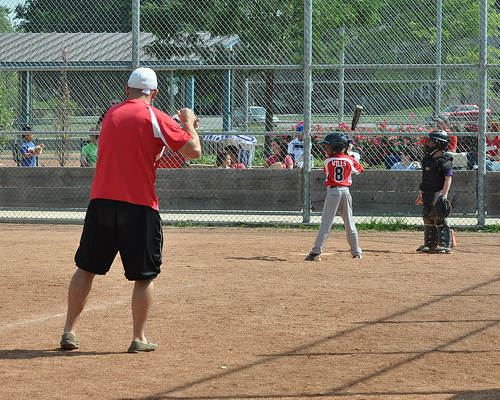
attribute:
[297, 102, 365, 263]
player — young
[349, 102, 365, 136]
bat — black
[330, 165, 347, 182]
number — #8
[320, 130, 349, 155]
helmet — black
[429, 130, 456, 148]
helmet — black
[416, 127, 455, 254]
catcher — young, standing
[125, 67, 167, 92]
hat — white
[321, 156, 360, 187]
shirt — white, red, black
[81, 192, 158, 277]
shorts — black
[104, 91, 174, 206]
shirt — red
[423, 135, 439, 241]
gear — protective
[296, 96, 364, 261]
batter — standing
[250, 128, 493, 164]
people — watching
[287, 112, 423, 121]
grass — strip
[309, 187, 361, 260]
pants — gray, grey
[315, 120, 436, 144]
rose bushes — growing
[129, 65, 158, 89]
cap — white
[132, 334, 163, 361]
shoe — grey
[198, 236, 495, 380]
dirt — brown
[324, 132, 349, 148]
cap — blue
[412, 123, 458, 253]
umpire — dressed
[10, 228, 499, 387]
ground — dirt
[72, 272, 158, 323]
calves — large